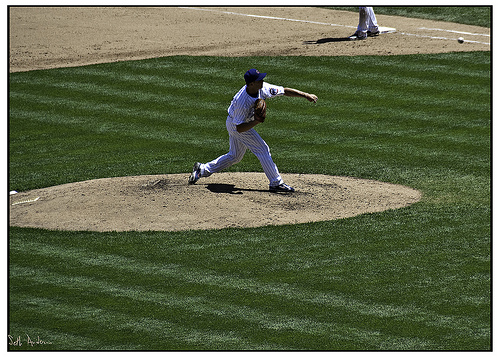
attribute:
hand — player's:
[307, 88, 321, 101]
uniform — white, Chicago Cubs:
[185, 54, 337, 209]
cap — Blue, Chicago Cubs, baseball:
[241, 67, 273, 87]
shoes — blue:
[187, 161, 299, 195]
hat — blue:
[241, 67, 267, 81]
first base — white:
[356, 16, 399, 42]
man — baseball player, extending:
[188, 63, 320, 194]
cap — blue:
[243, 67, 267, 83]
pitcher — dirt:
[172, 65, 294, 180]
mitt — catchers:
[247, 96, 274, 129]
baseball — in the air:
[447, 25, 477, 51]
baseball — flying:
[457, 35, 462, 42]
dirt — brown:
[11, 165, 422, 232]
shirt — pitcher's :
[226, 79, 284, 126]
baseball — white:
[449, 32, 481, 62]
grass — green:
[8, 57, 488, 344]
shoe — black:
[265, 174, 301, 201]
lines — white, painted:
[179, 5, 489, 47]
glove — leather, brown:
[251, 93, 270, 127]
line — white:
[184, 0, 440, 53]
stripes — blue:
[232, 120, 282, 185]